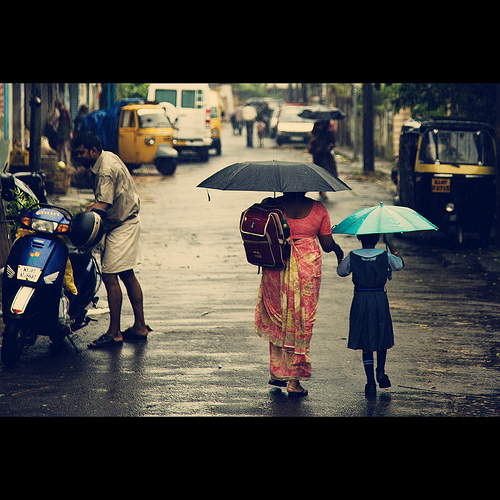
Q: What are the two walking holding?
A: Umbrellas.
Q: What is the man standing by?
A: Scooter.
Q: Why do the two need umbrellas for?
A: Rain.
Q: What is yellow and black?
A: Vehicle.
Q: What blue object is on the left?
A: Scooter.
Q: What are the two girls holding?
A: Umbrellas.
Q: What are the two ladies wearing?
A: Dresses.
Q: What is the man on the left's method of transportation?
A: Scooter.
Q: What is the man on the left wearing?
A: Khaki outfit.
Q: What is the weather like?
A: Rainy.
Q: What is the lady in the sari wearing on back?
A: Backpack.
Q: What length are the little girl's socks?
A: Almost knee high.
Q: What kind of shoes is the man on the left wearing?
A: Sandals.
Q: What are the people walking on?
A: The road.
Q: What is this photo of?
A: A wet street.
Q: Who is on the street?
A: Lots of people.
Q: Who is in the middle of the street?
A: Two women.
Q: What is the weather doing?
A: Raining.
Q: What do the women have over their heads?
A: Umbrellas.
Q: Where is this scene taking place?
A: On a little city street.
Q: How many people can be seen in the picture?
A: 10.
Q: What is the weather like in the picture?
A: It's rainy.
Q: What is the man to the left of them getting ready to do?
A: Take off on his scooter.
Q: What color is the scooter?
A: Blue.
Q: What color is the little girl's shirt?
A: Teal.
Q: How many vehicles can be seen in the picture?
A: 7.